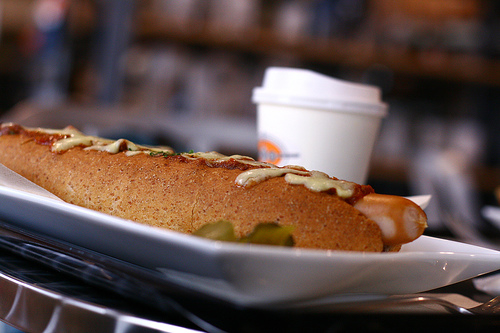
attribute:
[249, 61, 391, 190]
cup — white, gray, orange, paper, closed, disposable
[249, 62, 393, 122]
lid — white, plastic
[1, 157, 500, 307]
plate — white, shiny, rectangle, clean, ceramic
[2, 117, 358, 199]
cheese — melted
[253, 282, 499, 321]
spoon — shiny, silver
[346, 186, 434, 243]
hot dog — brown, creamy, long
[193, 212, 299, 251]
pickles — green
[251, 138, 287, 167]
logo — orange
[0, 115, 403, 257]
bread — large, brown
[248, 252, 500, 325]
utensil — fork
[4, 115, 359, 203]
mayo — beige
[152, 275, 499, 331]
silverware — shiny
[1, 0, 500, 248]
background — blurry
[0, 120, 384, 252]
crust — brown